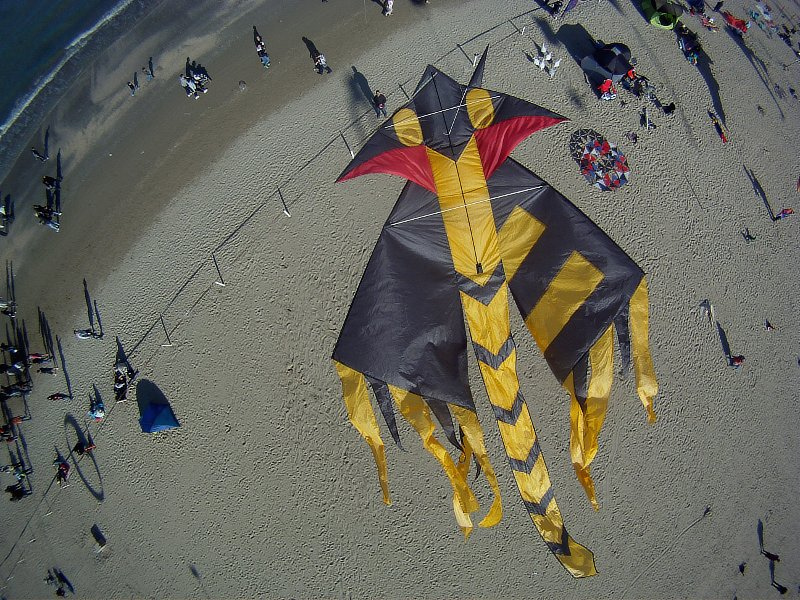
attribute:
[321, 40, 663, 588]
kite — red, silver, yellow, in the air, big, black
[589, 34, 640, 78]
umbrella — black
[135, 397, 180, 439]
umbrella — blue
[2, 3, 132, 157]
water — blue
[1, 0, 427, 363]
sand — wet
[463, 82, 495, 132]
eye — golden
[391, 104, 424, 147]
eye — golden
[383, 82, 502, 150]
eyes — yellow